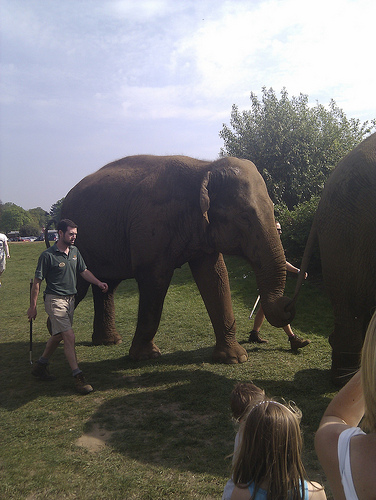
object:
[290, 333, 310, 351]
boot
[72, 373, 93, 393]
shoes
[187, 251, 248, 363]
elephant leg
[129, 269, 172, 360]
elephant leg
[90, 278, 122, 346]
elephant leg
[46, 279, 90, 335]
elephant leg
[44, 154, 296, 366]
elephant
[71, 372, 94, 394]
boot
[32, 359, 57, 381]
boot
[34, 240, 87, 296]
shirt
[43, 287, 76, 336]
shorts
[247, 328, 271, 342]
boot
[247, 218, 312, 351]
human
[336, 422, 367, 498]
garment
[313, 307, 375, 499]
woman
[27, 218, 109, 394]
man